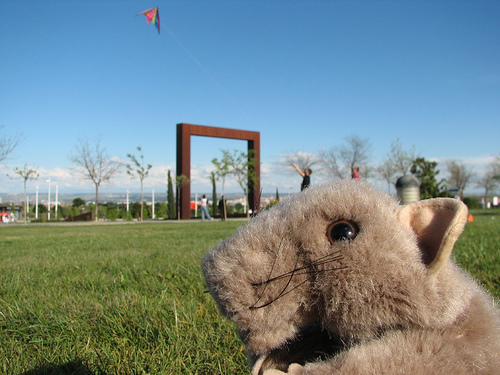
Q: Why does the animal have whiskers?
A: For feeling things.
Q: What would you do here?
A: Walk around.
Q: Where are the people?
A: Behind the stuffed animal.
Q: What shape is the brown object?
A: Square.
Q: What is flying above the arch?
A: Rainbow kite.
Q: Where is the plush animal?
A: In front of the camera.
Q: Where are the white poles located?
A: In the background, before the horizon.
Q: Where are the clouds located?
A: At the horizon.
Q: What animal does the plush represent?
A: Mouse.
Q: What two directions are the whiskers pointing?
A: Up and right.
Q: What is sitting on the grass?
A: Brown plush mouse.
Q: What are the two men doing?
A: Flying a kite.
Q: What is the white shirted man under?
A: A brown structure.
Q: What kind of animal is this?
A: A stuffed animal.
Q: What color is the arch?
A: Brown.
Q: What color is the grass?
A: Green.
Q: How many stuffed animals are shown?
A: One.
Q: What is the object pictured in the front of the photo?
A: Stuffed Animal.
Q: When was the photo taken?
A: Daytime.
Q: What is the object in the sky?
A: A kite.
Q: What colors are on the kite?
A: Red, green, and black.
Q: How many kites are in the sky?
A: One.